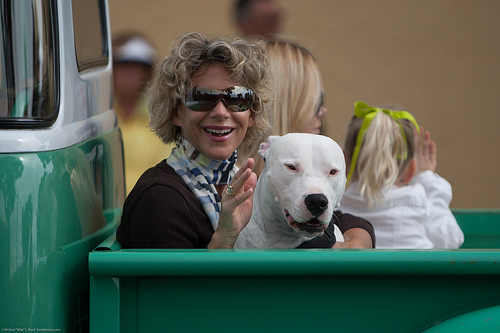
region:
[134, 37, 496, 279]
group of people sitting in back of truck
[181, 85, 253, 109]
sunglasses on woman's face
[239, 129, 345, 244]
white dog sitting in truck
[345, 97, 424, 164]
yellow ribbons on girls head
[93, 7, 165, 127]
man standing in background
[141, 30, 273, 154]
curly blond hair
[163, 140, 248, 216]
multi colored checkered scarf on woman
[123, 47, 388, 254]
woman holding dog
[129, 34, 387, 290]
dog being held by a woman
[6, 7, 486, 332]
turquoise truck carrying people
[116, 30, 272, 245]
woman smiling and waving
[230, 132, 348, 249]
dog riding in the back of a pickup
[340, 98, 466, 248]
the back of a little girl waving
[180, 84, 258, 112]
a woman's reflective sunglasses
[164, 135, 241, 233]
a woman's stripped scarf wrapped around her neck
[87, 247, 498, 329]
the bed of a green pickup truck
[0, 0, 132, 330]
the cab of a green pickup truck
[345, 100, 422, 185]
a yellow ribbon tied in a girl's hair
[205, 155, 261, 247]
a woman's hand with a ring on it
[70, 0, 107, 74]
the back window of a pickup truck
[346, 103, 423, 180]
a little girl with a green ribbon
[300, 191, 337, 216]
black nose of a white dog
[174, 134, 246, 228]
a woman wearing a striped scarf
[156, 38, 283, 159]
a woman with blonde curly hair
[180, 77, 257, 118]
a woman wearing sunglasses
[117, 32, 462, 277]
three people and a dog in the back of a truck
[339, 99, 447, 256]
a little girl wearing a white coat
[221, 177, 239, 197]
a woman wearing a ring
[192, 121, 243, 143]
smile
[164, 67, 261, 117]
woman is wearing sun glasses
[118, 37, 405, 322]
woman is holding a dog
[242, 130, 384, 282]
the dog is white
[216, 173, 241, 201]
woman is wearing ring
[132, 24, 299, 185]
the woman is smiling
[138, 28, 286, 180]
woman's hair is curly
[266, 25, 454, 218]
woman holding a little girl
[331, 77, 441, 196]
girl has green hair ribbon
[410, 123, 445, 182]
girl's hand is up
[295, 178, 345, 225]
dog's nose is black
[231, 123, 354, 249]
White dog with mouth slightly open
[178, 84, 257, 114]
Large, reflective dark shades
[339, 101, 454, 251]
Blonde hair of a child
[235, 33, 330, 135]
Person with blonde hair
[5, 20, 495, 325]
Three people and a dog in a truck's back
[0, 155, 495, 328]
Green color of a truck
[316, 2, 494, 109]
Hazy brown color of the background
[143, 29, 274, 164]
Smiling face of a person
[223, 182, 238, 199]
Ring on a finger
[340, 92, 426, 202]
Little girl with a green band stapping the hair